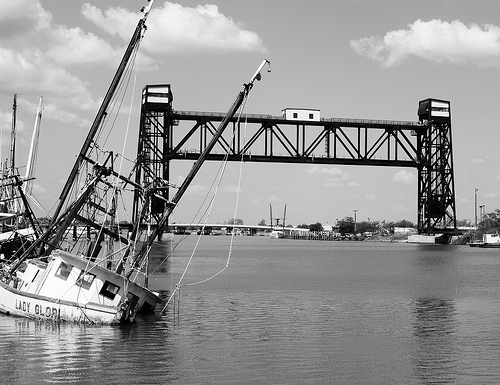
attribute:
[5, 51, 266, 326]
ship — broken, named, sinking, tipped, white, tilted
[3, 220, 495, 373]
water — dark, calm, serene, tranquil, sedate, pleasant, subdued, clear, reflecting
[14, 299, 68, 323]
lady glori — written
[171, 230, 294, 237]
boats — grouped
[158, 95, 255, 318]
ropes — dragging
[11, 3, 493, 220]
sky — light, mostly clear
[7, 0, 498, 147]
clouds — white, fluffy, puffy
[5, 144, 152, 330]
boats — white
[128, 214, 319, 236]
bridge — white, long, black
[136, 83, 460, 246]
bridge — tall, black, metal, meal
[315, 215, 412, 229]
trees — grouped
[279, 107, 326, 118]
building — small, white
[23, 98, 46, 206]
sail — white